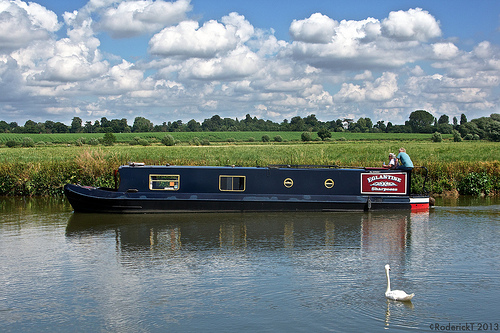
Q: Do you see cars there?
A: No, there are no cars.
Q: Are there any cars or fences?
A: No, there are no cars or fences.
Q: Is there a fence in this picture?
A: No, there are no fences.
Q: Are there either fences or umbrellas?
A: No, there are no fences or umbrellas.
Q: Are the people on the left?
A: No, the people are on the right of the image.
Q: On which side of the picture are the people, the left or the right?
A: The people are on the right of the image.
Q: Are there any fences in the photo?
A: No, there are no fences.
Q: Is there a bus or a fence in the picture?
A: No, there are no fences or buses.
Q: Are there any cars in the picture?
A: No, there are no cars.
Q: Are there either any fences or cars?
A: No, there are no cars or fences.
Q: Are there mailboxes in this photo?
A: No, there are no mailboxes.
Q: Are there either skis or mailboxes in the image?
A: No, there are no mailboxes or skis.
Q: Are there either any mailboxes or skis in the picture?
A: No, there are no mailboxes or skis.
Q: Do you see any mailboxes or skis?
A: No, there are no mailboxes or skis.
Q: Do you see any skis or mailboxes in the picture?
A: No, there are no mailboxes or skis.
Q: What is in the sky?
A: The clouds are in the sky.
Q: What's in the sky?
A: The clouds are in the sky.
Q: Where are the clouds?
A: The clouds are in the sky.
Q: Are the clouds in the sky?
A: Yes, the clouds are in the sky.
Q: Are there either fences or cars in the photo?
A: No, there are no cars or fences.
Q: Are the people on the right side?
A: Yes, the people are on the right of the image.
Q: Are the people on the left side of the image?
A: No, the people are on the right of the image.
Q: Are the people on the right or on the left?
A: The people are on the right of the image.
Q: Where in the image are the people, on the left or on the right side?
A: The people are on the right of the image.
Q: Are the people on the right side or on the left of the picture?
A: The people are on the right of the image.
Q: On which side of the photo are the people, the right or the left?
A: The people are on the right of the image.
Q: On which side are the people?
A: The people are on the right of the image.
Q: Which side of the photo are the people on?
A: The people are on the right of the image.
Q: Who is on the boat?
A: The people are on the boat.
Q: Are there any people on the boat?
A: Yes, there are people on the boat.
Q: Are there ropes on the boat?
A: No, there are people on the boat.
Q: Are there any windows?
A: Yes, there is a window.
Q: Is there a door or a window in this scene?
A: Yes, there is a window.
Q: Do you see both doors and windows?
A: No, there is a window but no doors.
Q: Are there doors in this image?
A: No, there are no doors.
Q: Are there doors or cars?
A: No, there are no doors or cars.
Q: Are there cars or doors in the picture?
A: No, there are no doors or cars.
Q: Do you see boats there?
A: Yes, there is a boat.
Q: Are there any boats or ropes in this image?
A: Yes, there is a boat.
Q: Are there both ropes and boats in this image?
A: No, there is a boat but no ropes.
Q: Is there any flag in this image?
A: No, there are no flags.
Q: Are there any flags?
A: No, there are no flags.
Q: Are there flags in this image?
A: No, there are no flags.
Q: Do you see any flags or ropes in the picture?
A: No, there are no flags or ropes.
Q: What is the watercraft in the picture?
A: The watercraft is a boat.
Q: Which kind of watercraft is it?
A: The watercraft is a boat.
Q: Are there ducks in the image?
A: Yes, there is a duck.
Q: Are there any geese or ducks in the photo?
A: Yes, there is a duck.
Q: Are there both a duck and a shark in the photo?
A: No, there is a duck but no sharks.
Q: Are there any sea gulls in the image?
A: No, there are no sea gulls.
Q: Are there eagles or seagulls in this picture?
A: No, there are no seagulls or eagles.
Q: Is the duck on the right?
A: Yes, the duck is on the right of the image.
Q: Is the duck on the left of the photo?
A: No, the duck is on the right of the image.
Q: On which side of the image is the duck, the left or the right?
A: The duck is on the right of the image.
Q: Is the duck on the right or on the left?
A: The duck is on the right of the image.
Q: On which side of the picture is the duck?
A: The duck is on the right of the image.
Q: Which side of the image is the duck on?
A: The duck is on the right of the image.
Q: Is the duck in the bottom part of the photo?
A: Yes, the duck is in the bottom of the image.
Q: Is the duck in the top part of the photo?
A: No, the duck is in the bottom of the image.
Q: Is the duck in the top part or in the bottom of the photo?
A: The duck is in the bottom of the image.